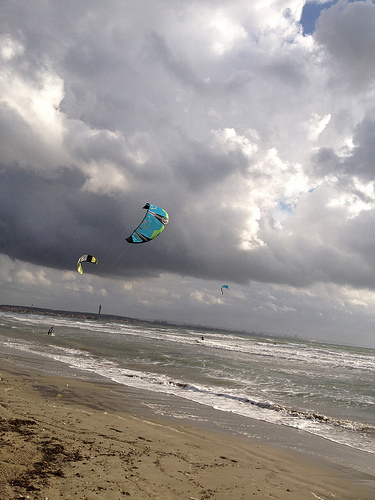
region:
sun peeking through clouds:
[163, 107, 296, 228]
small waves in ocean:
[81, 335, 266, 426]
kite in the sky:
[178, 271, 264, 309]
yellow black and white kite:
[65, 253, 109, 287]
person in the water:
[39, 323, 72, 347]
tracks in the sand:
[57, 406, 174, 482]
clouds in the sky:
[120, 265, 176, 313]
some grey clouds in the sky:
[135, 256, 219, 300]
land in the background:
[44, 292, 143, 335]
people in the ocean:
[36, 298, 264, 404]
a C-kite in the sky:
[114, 194, 177, 254]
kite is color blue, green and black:
[108, 189, 177, 254]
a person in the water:
[43, 319, 62, 344]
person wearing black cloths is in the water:
[195, 327, 212, 344]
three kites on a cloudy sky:
[1, 149, 369, 311]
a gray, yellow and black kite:
[68, 246, 101, 280]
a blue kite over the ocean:
[217, 270, 235, 303]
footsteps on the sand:
[97, 411, 244, 466]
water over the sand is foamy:
[85, 357, 308, 444]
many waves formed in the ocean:
[126, 318, 374, 374]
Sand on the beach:
[0, 364, 210, 498]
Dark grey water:
[76, 348, 362, 430]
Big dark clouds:
[8, 231, 336, 315]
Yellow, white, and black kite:
[69, 230, 107, 282]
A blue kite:
[212, 269, 237, 318]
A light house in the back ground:
[82, 277, 118, 330]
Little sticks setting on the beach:
[0, 411, 88, 498]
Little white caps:
[50, 348, 278, 433]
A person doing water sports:
[29, 309, 104, 355]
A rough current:
[34, 309, 280, 364]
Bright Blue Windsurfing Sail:
[125, 193, 179, 256]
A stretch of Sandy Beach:
[9, 364, 285, 498]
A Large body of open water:
[229, 332, 374, 433]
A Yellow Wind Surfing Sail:
[68, 246, 104, 280]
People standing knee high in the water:
[40, 320, 65, 339]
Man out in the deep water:
[198, 326, 217, 343]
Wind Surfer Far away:
[263, 335, 287, 353]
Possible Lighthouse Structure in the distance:
[95, 302, 108, 320]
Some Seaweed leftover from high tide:
[0, 411, 73, 494]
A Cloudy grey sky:
[179, 132, 363, 253]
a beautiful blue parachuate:
[106, 181, 177, 250]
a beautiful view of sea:
[39, 305, 360, 470]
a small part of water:
[141, 365, 330, 430]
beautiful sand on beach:
[25, 412, 307, 498]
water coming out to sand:
[100, 363, 357, 465]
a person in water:
[34, 323, 66, 339]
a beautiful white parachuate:
[68, 235, 117, 289]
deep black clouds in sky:
[6, 174, 359, 273]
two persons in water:
[38, 295, 174, 359]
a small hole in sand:
[17, 430, 81, 497]